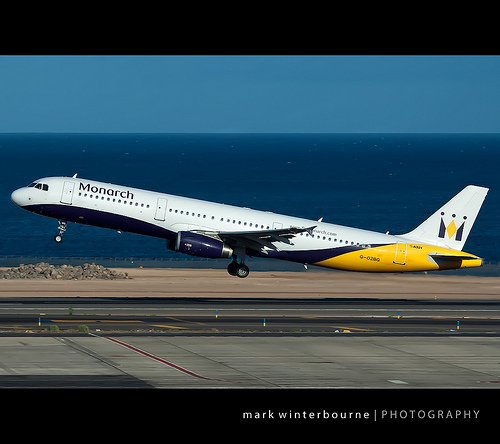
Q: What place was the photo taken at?
A: It was taken at the ocean.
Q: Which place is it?
A: It is an ocean.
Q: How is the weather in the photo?
A: It is clear.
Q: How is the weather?
A: It is clear.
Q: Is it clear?
A: Yes, it is clear.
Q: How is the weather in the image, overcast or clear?
A: It is clear.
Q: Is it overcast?
A: No, it is clear.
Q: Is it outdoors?
A: Yes, it is outdoors.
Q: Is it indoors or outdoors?
A: It is outdoors.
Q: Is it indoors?
A: No, it is outdoors.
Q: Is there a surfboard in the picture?
A: No, there are no surfboards.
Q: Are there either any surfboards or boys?
A: No, there are no surfboards or boys.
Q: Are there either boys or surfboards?
A: No, there are no surfboards or boys.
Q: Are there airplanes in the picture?
A: Yes, there is an airplane.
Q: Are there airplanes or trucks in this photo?
A: Yes, there is an airplane.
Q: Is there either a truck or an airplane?
A: Yes, there is an airplane.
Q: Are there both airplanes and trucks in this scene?
A: No, there is an airplane but no trucks.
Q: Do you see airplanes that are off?
A: Yes, there is an airplane that is off.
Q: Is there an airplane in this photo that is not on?
A: Yes, there is an airplane that is off.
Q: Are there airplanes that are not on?
A: Yes, there is an airplane that is off.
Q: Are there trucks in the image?
A: No, there are no trucks.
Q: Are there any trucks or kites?
A: No, there are no trucks or kites.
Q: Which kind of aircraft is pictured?
A: The aircraft is an airplane.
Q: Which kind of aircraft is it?
A: The aircraft is an airplane.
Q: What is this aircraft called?
A: This is an airplane.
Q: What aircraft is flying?
A: The aircraft is an airplane.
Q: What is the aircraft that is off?
A: The aircraft is an airplane.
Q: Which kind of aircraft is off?
A: The aircraft is an airplane.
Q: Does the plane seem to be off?
A: Yes, the plane is off.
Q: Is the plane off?
A: Yes, the plane is off.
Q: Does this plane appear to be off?
A: Yes, the plane is off.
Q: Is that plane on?
A: No, the plane is off.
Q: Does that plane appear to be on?
A: No, the plane is off.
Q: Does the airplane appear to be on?
A: No, the airplane is off.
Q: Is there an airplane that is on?
A: No, there is an airplane but it is off.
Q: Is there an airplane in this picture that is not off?
A: No, there is an airplane but it is off.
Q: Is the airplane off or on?
A: The airplane is off.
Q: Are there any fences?
A: No, there are no fences.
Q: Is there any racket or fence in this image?
A: No, there are no fences or rackets.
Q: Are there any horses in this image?
A: No, there are no horses.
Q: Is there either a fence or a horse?
A: No, there are no horses or fences.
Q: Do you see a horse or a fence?
A: No, there are no horses or fences.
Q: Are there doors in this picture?
A: Yes, there is a door.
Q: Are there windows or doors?
A: Yes, there is a door.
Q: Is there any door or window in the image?
A: Yes, there is a door.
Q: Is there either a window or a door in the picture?
A: Yes, there is a door.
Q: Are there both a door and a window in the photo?
A: Yes, there are both a door and a window.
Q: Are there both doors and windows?
A: Yes, there are both a door and a window.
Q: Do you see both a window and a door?
A: Yes, there are both a door and a window.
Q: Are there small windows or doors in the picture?
A: Yes, there is a small door.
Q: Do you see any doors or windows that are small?
A: Yes, the door is small.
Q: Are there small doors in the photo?
A: Yes, there is a small door.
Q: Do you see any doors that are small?
A: Yes, there is a door that is small.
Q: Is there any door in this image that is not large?
A: Yes, there is a small door.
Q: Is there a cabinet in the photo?
A: No, there are no cabinets.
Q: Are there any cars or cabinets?
A: No, there are no cabinets or cars.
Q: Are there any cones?
A: No, there are no cones.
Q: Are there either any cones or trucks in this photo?
A: No, there are no cones or trucks.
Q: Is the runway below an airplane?
A: Yes, the runway is below an airplane.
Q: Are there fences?
A: No, there are no fences.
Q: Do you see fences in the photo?
A: No, there are no fences.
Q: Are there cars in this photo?
A: No, there are no cars.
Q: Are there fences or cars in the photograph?
A: No, there are no cars or fences.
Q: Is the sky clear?
A: Yes, the sky is clear.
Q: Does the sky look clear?
A: Yes, the sky is clear.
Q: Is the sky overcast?
A: No, the sky is clear.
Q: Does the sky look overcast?
A: No, the sky is clear.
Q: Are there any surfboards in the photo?
A: No, there are no surfboards.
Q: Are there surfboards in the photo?
A: No, there are no surfboards.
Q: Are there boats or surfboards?
A: No, there are no surfboards or boats.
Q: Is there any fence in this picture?
A: No, there are no fences.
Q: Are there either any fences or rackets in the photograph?
A: No, there are no fences or rackets.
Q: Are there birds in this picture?
A: No, there are no birds.